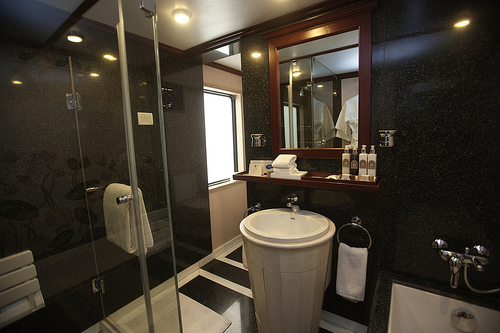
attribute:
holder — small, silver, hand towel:
[312, 208, 390, 268]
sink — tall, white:
[233, 200, 333, 332]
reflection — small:
[308, 97, 333, 145]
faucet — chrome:
[371, 231, 498, 331]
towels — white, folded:
[273, 149, 298, 179]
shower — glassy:
[154, 15, 214, 332]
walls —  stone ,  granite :
[239, 3, 499, 331]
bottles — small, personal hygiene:
[339, 139, 377, 181]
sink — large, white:
[237, 209, 332, 332]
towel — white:
[332, 238, 365, 308]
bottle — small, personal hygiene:
[340, 145, 350, 176]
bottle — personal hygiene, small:
[76, 149, 136, 184]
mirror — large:
[264, 4, 372, 168]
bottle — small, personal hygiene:
[333, 143, 349, 180]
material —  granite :
[19, 106, 39, 135]